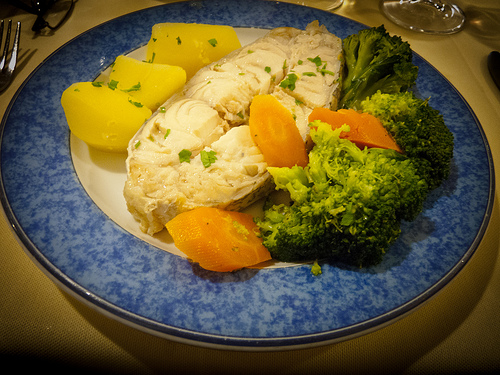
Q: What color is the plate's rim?
A: Blue.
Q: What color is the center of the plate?
A: White.